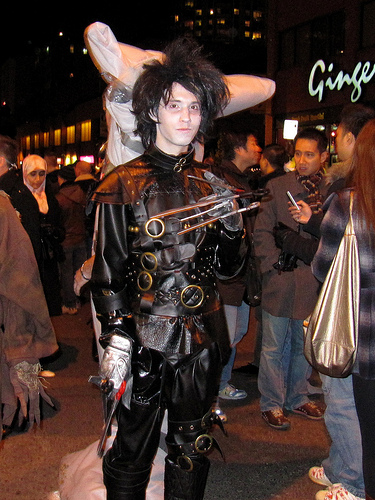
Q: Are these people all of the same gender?
A: No, they are both male and female.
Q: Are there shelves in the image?
A: No, there are no shelves.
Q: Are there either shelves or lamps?
A: No, there are no shelves or lamps.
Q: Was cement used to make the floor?
A: Yes, the floor is made of cement.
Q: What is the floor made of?
A: The floor is made of concrete.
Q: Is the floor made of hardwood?
A: No, the floor is made of concrete.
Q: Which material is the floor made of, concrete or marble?
A: The floor is made of concrete.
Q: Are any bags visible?
A: Yes, there is a bag.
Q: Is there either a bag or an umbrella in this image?
A: Yes, there is a bag.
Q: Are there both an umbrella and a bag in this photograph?
A: No, there is a bag but no umbrellas.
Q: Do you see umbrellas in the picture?
A: No, there are no umbrellas.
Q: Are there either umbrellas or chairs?
A: No, there are no umbrellas or chairs.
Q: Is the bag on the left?
A: No, the bag is on the right of the image.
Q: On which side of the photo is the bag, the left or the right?
A: The bag is on the right of the image.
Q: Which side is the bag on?
A: The bag is on the right of the image.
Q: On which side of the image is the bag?
A: The bag is on the right of the image.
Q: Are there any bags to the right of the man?
A: Yes, there is a bag to the right of the man.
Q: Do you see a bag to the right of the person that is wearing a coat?
A: Yes, there is a bag to the right of the man.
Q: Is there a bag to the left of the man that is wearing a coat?
A: No, the bag is to the right of the man.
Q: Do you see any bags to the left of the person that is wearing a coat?
A: No, the bag is to the right of the man.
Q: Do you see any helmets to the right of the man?
A: No, there is a bag to the right of the man.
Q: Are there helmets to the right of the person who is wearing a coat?
A: No, there is a bag to the right of the man.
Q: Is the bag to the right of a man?
A: Yes, the bag is to the right of a man.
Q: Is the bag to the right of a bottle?
A: No, the bag is to the right of a man.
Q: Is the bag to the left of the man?
A: No, the bag is to the right of the man.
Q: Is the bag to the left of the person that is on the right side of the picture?
A: No, the bag is to the right of the man.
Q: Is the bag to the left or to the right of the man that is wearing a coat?
A: The bag is to the right of the man.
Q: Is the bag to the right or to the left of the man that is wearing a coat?
A: The bag is to the right of the man.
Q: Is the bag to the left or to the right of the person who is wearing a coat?
A: The bag is to the right of the man.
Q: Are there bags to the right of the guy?
A: Yes, there is a bag to the right of the guy.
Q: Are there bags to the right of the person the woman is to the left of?
A: Yes, there is a bag to the right of the guy.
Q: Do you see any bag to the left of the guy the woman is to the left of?
A: No, the bag is to the right of the guy.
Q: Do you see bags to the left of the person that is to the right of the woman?
A: No, the bag is to the right of the guy.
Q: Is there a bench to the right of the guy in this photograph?
A: No, there is a bag to the right of the guy.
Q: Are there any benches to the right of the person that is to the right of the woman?
A: No, there is a bag to the right of the guy.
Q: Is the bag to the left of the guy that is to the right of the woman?
A: No, the bag is to the right of the guy.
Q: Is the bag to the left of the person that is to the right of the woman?
A: No, the bag is to the right of the guy.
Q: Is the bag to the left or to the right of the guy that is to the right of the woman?
A: The bag is to the right of the guy.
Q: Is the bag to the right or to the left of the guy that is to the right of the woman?
A: The bag is to the right of the guy.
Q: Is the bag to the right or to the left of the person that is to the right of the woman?
A: The bag is to the right of the guy.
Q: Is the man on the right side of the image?
A: Yes, the man is on the right of the image.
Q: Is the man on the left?
A: No, the man is on the right of the image.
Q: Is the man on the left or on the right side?
A: The man is on the right of the image.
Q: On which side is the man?
A: The man is on the right of the image.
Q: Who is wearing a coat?
A: The man is wearing a coat.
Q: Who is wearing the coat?
A: The man is wearing a coat.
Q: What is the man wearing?
A: The man is wearing a coat.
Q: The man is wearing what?
A: The man is wearing a coat.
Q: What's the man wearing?
A: The man is wearing a coat.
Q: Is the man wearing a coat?
A: Yes, the man is wearing a coat.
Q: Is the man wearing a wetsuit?
A: No, the man is wearing a coat.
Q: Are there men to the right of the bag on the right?
A: No, the man is to the left of the bag.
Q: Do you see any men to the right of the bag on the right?
A: No, the man is to the left of the bag.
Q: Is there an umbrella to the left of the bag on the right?
A: No, there is a man to the left of the bag.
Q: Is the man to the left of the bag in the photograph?
A: Yes, the man is to the left of the bag.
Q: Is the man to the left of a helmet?
A: No, the man is to the left of the bag.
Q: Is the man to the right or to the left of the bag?
A: The man is to the left of the bag.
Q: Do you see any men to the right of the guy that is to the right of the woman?
A: Yes, there is a man to the right of the guy.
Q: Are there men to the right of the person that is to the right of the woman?
A: Yes, there is a man to the right of the guy.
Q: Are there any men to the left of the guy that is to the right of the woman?
A: No, the man is to the right of the guy.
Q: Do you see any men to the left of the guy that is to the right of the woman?
A: No, the man is to the right of the guy.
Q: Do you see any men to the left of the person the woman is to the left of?
A: No, the man is to the right of the guy.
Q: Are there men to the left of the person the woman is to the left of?
A: No, the man is to the right of the guy.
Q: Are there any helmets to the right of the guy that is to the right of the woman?
A: No, there is a man to the right of the guy.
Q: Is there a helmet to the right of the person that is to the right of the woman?
A: No, there is a man to the right of the guy.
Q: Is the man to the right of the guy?
A: Yes, the man is to the right of the guy.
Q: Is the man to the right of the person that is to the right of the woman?
A: Yes, the man is to the right of the guy.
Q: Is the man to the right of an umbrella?
A: No, the man is to the right of the guy.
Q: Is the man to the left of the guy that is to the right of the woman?
A: No, the man is to the right of the guy.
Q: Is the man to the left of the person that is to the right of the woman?
A: No, the man is to the right of the guy.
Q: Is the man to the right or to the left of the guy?
A: The man is to the right of the guy.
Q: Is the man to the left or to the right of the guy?
A: The man is to the right of the guy.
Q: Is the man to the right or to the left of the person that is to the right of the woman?
A: The man is to the right of the guy.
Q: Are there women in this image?
A: Yes, there is a woman.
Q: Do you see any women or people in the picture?
A: Yes, there is a woman.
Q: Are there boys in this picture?
A: No, there are no boys.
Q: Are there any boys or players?
A: No, there are no boys or players.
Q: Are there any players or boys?
A: No, there are no boys or players.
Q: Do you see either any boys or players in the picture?
A: No, there are no boys or players.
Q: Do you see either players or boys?
A: No, there are no boys or players.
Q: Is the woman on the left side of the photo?
A: Yes, the woman is on the left of the image.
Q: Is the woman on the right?
A: No, the woman is on the left of the image.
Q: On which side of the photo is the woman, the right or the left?
A: The woman is on the left of the image.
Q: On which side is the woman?
A: The woman is on the left of the image.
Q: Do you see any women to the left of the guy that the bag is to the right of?
A: Yes, there is a woman to the left of the guy.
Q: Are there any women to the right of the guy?
A: No, the woman is to the left of the guy.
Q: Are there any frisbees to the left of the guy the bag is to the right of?
A: No, there is a woman to the left of the guy.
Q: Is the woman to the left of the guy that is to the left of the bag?
A: Yes, the woman is to the left of the guy.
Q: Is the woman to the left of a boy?
A: No, the woman is to the left of the guy.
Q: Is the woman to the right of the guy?
A: No, the woman is to the left of the guy.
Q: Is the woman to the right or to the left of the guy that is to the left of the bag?
A: The woman is to the left of the guy.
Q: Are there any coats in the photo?
A: Yes, there is a coat.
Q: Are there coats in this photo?
A: Yes, there is a coat.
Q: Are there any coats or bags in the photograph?
A: Yes, there is a coat.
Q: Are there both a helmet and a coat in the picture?
A: No, there is a coat but no helmets.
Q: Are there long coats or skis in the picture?
A: Yes, there is a long coat.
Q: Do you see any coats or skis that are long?
A: Yes, the coat is long.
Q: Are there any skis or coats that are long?
A: Yes, the coat is long.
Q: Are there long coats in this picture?
A: Yes, there is a long coat.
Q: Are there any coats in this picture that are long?
A: Yes, there is a coat that is long.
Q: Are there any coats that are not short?
A: Yes, there is a long coat.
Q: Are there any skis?
A: No, there are no skis.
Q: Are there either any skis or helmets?
A: No, there are no skis or helmets.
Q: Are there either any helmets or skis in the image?
A: No, there are no skis or helmets.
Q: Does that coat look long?
A: Yes, the coat is long.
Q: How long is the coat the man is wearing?
A: The coat is long.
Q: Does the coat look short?
A: No, the coat is long.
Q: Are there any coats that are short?
A: No, there is a coat but it is long.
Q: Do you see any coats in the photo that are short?
A: No, there is a coat but it is long.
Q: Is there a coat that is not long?
A: No, there is a coat but it is long.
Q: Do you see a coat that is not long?
A: No, there is a coat but it is long.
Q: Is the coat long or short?
A: The coat is long.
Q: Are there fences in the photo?
A: No, there are no fences.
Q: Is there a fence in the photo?
A: No, there are no fences.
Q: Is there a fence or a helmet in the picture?
A: No, there are no fences or helmets.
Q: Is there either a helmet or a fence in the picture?
A: No, there are no fences or helmets.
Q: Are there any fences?
A: No, there are no fences.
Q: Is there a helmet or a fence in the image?
A: No, there are no fences or helmets.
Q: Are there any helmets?
A: No, there are no helmets.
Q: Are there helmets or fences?
A: No, there are no helmets or fences.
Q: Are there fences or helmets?
A: No, there are no helmets or fences.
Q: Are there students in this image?
A: No, there are no students.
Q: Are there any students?
A: No, there are no students.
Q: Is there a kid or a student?
A: No, there are no students or children.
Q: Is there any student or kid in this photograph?
A: No, there are no students or children.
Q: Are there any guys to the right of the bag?
A: No, the guy is to the left of the bag.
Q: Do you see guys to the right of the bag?
A: No, the guy is to the left of the bag.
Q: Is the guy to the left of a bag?
A: Yes, the guy is to the left of a bag.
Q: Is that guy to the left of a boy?
A: No, the guy is to the left of a bag.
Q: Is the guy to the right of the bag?
A: No, the guy is to the left of the bag.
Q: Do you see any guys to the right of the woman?
A: Yes, there is a guy to the right of the woman.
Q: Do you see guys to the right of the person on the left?
A: Yes, there is a guy to the right of the woman.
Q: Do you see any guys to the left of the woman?
A: No, the guy is to the right of the woman.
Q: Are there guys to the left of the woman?
A: No, the guy is to the right of the woman.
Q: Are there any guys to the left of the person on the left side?
A: No, the guy is to the right of the woman.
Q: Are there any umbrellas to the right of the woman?
A: No, there is a guy to the right of the woman.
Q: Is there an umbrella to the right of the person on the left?
A: No, there is a guy to the right of the woman.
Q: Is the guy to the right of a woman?
A: Yes, the guy is to the right of a woman.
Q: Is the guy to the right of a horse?
A: No, the guy is to the right of a woman.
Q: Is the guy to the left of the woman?
A: No, the guy is to the right of the woman.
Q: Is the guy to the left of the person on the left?
A: No, the guy is to the right of the woman.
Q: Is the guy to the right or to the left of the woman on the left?
A: The guy is to the right of the woman.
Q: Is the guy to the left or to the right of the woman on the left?
A: The guy is to the right of the woman.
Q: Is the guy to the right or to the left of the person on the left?
A: The guy is to the right of the woman.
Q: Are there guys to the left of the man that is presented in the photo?
A: Yes, there is a guy to the left of the man.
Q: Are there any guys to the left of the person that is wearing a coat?
A: Yes, there is a guy to the left of the man.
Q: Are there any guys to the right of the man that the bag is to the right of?
A: No, the guy is to the left of the man.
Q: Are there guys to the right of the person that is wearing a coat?
A: No, the guy is to the left of the man.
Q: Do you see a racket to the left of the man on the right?
A: No, there is a guy to the left of the man.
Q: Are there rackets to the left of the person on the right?
A: No, there is a guy to the left of the man.